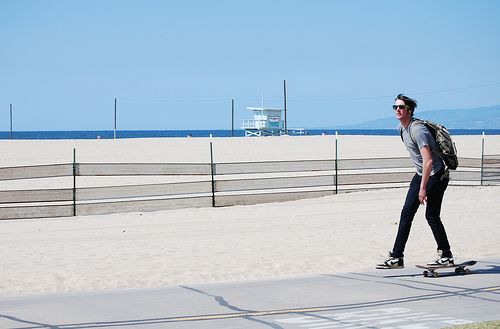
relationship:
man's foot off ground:
[373, 252, 404, 273] [2, 134, 496, 325]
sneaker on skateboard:
[427, 255, 458, 269] [416, 255, 480, 277]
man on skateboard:
[374, 94, 455, 273] [415, 256, 479, 275]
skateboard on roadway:
[413, 259, 484, 275] [1, 260, 496, 326]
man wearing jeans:
[374, 94, 455, 273] [389, 167, 450, 257]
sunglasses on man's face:
[393, 101, 407, 111] [393, 99, 405, 119]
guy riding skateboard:
[377, 89, 461, 269] [416, 255, 480, 277]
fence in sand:
[0, 153, 499, 216] [2, 131, 494, 297]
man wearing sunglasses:
[374, 94, 455, 273] [389, 102, 408, 112]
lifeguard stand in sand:
[240, 103, 288, 133] [2, 131, 494, 297]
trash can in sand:
[207, 128, 214, 139] [0, 130, 495, 161]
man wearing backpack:
[374, 94, 455, 273] [417, 113, 459, 170]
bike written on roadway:
[288, 300, 468, 326] [1, 260, 496, 326]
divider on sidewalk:
[83, 283, 497, 324] [2, 252, 498, 326]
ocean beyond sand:
[4, 130, 495, 139] [2, 131, 494, 297]